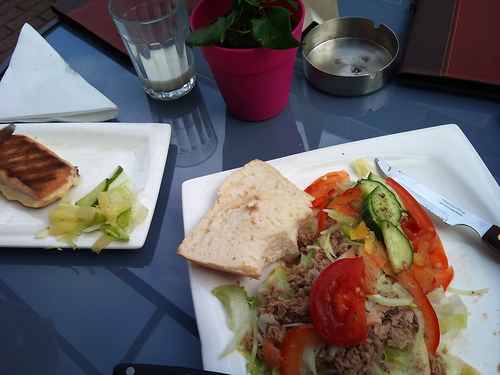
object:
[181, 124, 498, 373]
plate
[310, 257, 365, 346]
food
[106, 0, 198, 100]
glass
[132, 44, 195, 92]
milk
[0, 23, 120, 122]
napkin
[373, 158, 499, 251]
knife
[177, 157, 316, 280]
bread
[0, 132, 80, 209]
bread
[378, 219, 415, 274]
cucumber slice